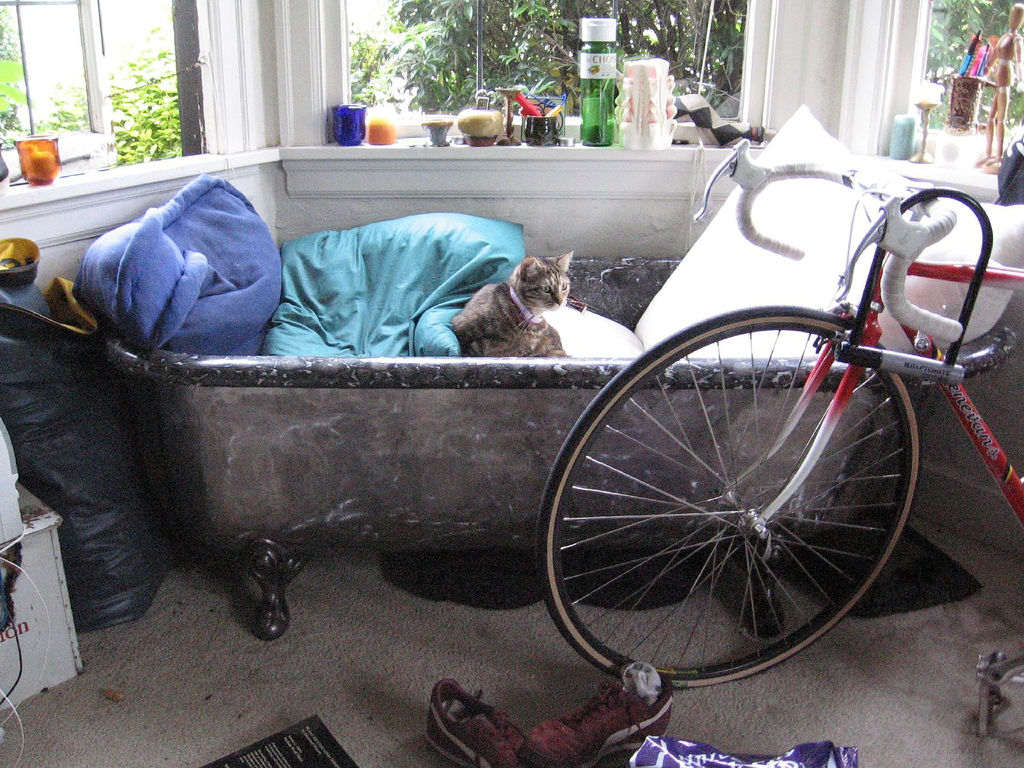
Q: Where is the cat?
A: In the tub.